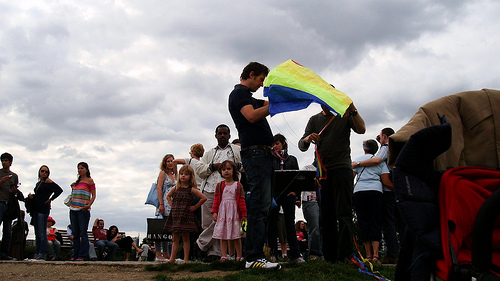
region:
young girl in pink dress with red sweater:
[206, 156, 253, 270]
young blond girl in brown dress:
[166, 161, 205, 266]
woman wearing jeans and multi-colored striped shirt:
[63, 157, 100, 268]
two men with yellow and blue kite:
[223, 51, 369, 278]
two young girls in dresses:
[163, 157, 251, 271]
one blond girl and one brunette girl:
[165, 158, 254, 272]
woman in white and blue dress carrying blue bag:
[142, 146, 179, 266]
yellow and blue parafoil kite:
[259, 60, 355, 155]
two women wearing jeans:
[23, 157, 100, 266]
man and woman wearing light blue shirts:
[353, 121, 406, 267]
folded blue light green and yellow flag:
[261, 56, 351, 123]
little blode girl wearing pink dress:
[211, 158, 244, 259]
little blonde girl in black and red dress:
[165, 165, 205, 261]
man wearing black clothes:
[197, 123, 242, 260]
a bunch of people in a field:
[6, 60, 400, 267]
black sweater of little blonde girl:
[210, 180, 248, 217]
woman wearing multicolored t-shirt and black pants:
[66, 159, 96, 256]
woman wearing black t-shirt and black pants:
[25, 163, 64, 253]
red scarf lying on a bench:
[437, 163, 494, 280]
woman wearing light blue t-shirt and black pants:
[351, 126, 399, 273]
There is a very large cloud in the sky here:
[376, 45, 397, 112]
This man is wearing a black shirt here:
[241, 81, 269, 136]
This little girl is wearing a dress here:
[173, 184, 210, 270]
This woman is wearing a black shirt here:
[33, 180, 53, 221]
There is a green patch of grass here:
[314, 258, 318, 276]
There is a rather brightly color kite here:
[288, 65, 332, 113]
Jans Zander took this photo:
[72, 3, 335, 273]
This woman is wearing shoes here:
[362, 253, 396, 278]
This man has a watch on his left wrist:
[353, 157, 360, 171]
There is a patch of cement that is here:
[127, 257, 139, 279]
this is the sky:
[74, 26, 165, 90]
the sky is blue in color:
[22, 23, 54, 40]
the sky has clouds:
[308, 0, 437, 52]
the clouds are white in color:
[351, 9, 461, 76]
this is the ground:
[72, 260, 119, 278]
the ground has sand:
[97, 268, 134, 279]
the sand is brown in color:
[64, 265, 124, 279]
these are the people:
[5, 58, 491, 250]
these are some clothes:
[280, 65, 312, 97]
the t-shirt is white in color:
[366, 167, 379, 192]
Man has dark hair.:
[238, 60, 264, 75]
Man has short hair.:
[231, 51, 283, 96]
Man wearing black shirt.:
[232, 96, 282, 134]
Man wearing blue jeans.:
[231, 157, 311, 257]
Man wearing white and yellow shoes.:
[239, 255, 284, 277]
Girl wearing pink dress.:
[221, 182, 258, 247]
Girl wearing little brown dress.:
[165, 187, 209, 240]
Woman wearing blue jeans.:
[63, 210, 102, 252]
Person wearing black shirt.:
[29, 181, 61, 210]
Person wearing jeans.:
[33, 208, 67, 269]